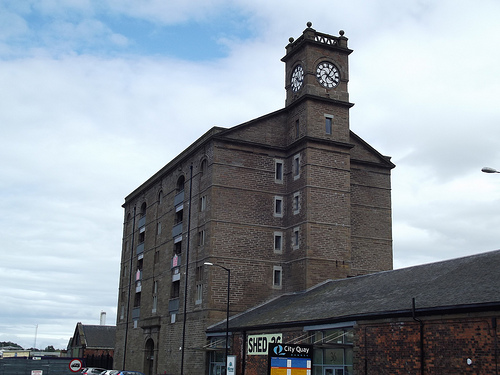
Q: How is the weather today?
A: It is overcast.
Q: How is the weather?
A: It is overcast.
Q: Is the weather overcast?
A: Yes, it is overcast.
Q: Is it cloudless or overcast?
A: It is overcast.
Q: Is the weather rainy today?
A: No, it is overcast.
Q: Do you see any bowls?
A: No, there are no bowls.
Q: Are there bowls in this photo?
A: No, there are no bowls.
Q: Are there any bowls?
A: No, there are no bowls.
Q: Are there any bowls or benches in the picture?
A: No, there are no bowls or benches.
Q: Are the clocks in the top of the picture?
A: Yes, the clocks are in the top of the image.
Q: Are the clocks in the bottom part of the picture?
A: No, the clocks are in the top of the image.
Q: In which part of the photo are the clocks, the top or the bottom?
A: The clocks are in the top of the image.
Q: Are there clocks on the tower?
A: Yes, there are clocks on the tower.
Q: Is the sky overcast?
A: Yes, the sky is overcast.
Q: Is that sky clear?
A: No, the sky is overcast.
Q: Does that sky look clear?
A: No, the sky is overcast.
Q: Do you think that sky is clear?
A: No, the sky is overcast.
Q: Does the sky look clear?
A: No, the sky is overcast.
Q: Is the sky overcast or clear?
A: The sky is overcast.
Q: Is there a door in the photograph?
A: Yes, there is a door.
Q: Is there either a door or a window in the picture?
A: Yes, there is a door.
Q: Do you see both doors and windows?
A: Yes, there are both a door and a window.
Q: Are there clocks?
A: Yes, there is a clock.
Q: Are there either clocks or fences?
A: Yes, there is a clock.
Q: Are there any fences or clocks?
A: Yes, there is a clock.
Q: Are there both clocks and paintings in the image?
A: No, there is a clock but no paintings.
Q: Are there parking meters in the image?
A: No, there are no parking meters.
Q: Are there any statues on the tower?
A: No, there is a clock on the tower.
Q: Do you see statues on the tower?
A: No, there is a clock on the tower.